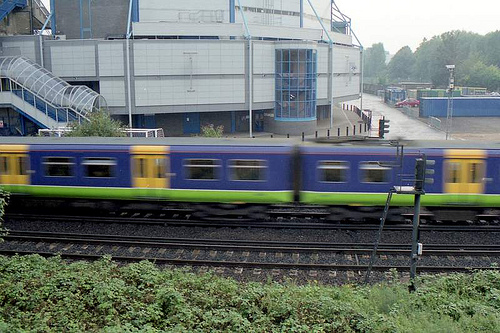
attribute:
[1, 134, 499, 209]
train — blue, yellow, moving, green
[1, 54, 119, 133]
staircase — covered, connected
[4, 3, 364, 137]
building — blue, white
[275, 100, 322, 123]
frames — blue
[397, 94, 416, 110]
car — red, parked, small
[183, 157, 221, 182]
window — rectangular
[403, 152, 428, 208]
stoplight — black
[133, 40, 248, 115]
wall — exterior, white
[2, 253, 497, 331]
shrub — green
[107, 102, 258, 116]
trim — gray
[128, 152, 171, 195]
doors — yellow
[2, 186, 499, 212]
border — green